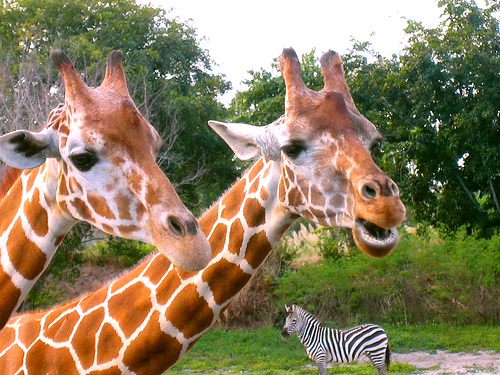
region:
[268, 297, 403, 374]
The zebra is black and white.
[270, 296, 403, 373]
The zebra is striped.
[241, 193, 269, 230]
The spot is brown.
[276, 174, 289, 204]
The spot is brown.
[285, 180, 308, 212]
The spot is brown.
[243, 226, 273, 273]
The spot is brown.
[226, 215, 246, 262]
The spot is brown.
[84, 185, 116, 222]
The spot is brown.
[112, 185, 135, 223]
The spot is brown.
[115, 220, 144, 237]
The spot is brown.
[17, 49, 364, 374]
two giraffes close together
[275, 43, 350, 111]
brown and black ossicles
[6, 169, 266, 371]
brown and white spots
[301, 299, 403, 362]
black and white zebra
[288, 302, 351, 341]
black and white mane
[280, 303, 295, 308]
black and white ears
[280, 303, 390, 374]
the zebra on the grass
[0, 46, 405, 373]
the two giraffe heads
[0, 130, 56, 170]
the ear on the giraffe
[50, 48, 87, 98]
the horn on the giraffe's head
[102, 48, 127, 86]
the horn on the giraffe's head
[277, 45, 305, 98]
the horn on the giraffe's head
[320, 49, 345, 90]
the horn on the giraffe's head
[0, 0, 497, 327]
the trees behind the animals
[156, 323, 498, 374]
the grass in the animal enclosure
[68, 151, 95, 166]
the eye on the giraffe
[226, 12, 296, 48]
this is the sky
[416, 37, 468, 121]
the leaves are green in color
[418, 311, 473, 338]
the grass is green in color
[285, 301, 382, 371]
this is a zebra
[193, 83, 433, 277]
this is a giraffe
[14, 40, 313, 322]
the giraffes are two in number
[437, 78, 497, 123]
green leaves on the tree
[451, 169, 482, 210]
green leaves on the tree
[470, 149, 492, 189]
green leaves on the tree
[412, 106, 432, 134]
green leaves on the tree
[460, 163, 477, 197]
green leaves on the tree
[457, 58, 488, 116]
green leaves on the tree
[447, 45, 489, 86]
green leaves on the tree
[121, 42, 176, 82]
green leaves on the tree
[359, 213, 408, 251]
Mouth of a giraffe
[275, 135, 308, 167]
Eye of a giraffe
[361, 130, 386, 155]
Eye of a giraffe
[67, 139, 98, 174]
Eye of a giraffe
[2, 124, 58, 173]
Ear of a giraffe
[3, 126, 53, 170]
Ear of a giraffe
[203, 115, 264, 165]
Ear of a giraffe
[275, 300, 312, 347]
Head of a zebra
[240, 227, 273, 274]
brown spot on the giraffe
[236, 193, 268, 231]
brown spot on the giraffe